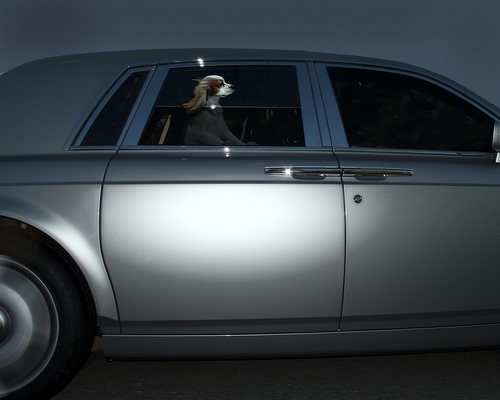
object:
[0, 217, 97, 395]
wheel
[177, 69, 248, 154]
dog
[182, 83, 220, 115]
ears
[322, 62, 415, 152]
window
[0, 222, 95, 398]
black tire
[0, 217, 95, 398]
rubber tire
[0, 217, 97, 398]
back tire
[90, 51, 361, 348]
door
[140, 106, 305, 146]
window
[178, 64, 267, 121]
dog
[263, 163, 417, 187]
handles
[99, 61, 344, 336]
door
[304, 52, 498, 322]
door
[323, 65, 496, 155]
tinted window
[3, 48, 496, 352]
grey car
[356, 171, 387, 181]
handle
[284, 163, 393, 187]
handle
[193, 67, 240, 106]
dog head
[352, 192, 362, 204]
key opening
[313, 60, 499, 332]
door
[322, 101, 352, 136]
ground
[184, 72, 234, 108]
head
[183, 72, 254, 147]
dog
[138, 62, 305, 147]
window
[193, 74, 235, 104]
head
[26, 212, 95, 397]
clock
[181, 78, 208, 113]
hair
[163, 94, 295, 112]
window edge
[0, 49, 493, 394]
chrome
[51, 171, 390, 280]
light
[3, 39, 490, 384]
car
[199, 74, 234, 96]
head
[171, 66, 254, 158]
dog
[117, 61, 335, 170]
window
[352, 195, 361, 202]
lock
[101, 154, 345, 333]
door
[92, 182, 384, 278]
light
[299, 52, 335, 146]
line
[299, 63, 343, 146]
panel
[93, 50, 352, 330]
door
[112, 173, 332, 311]
reflection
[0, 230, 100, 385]
wheel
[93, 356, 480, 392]
road